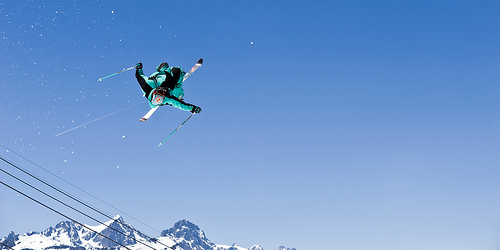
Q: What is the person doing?
A: A ski jump.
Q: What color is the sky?
A: Blue.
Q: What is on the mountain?
A: Snow.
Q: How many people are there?
A: One.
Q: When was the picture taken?
A: In the daytime.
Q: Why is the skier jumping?
A: Showing a trick.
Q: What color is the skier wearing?
A: Blue and black.